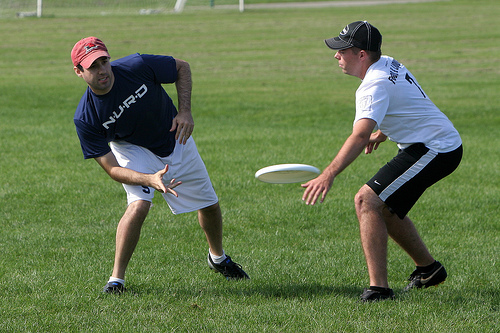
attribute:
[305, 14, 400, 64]
hat — black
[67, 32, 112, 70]
hat — red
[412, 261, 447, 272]
socks — black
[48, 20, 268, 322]
shorts — white 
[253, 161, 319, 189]
frisbee — white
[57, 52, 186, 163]
shirt — navy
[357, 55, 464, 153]
shirt — white 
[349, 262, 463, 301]
shoes — black , white 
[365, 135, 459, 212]
shorts — black 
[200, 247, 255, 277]
shoe — mans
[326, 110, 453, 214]
shorts — white 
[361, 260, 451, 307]
shoes — white , black 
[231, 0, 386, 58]
hat — red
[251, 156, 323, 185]
frisbee — white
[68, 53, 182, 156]
shirt — blue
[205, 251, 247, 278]
shoe — black 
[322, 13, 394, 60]
baseball hat — black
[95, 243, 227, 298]
socks — white 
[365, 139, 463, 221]
shorts — white, black 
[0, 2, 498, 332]
field — green, grassy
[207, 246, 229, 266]
sock — white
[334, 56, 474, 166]
shirt — white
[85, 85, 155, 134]
letters — white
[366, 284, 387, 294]
socks —  Man's,  black